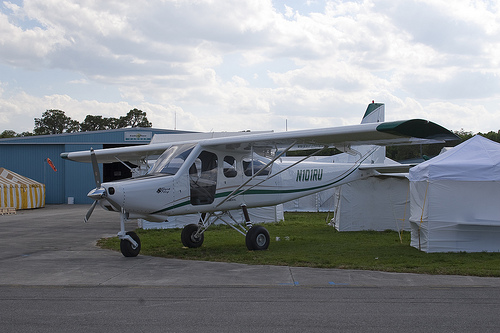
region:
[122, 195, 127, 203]
white paint on plane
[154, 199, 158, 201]
white paint on plane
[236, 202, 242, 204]
white paint on plane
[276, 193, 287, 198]
white paint on plane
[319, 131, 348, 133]
white paint on plane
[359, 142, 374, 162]
white paint on plane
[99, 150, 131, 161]
white paint on plane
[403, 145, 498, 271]
the tent is white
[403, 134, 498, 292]
the tent is white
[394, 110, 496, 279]
the tent is white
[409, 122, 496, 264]
the tent is white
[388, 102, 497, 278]
the tent is white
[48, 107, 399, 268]
a charter plane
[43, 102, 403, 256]
a charter plane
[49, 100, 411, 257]
a charter plane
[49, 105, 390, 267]
a charter plane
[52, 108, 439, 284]
a charter plane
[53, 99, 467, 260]
plane stays on ground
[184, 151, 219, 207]
plane has clear door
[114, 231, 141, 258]
wheel is attached to plane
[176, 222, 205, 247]
wheel is attached to plane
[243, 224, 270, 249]
wheel is attached to plane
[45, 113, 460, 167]
wing is attached to plane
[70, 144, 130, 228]
propeller is attached to plane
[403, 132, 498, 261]
tent is next to plane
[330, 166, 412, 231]
tent is next to plane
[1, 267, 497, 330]
ground is paved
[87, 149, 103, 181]
PROPELLAR OF AIR PL;ANE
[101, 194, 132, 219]
PROPELLAR OF AIR PLANE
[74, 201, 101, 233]
PROPELLAR OF AIR PLANE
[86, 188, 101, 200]
NOSE OF AIR PLANE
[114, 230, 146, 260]
WHEEL OF AIR PLANE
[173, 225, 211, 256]
WHEEL OF AIR PLANE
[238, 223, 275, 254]
WHEEL OF AIR PLANE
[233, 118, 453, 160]
WING OF AIR PLANE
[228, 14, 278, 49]
PUFFY CLOUDS IN THE SKY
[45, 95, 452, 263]
white plane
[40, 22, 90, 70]
white clouds in blue sky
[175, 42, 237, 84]
white clouds in blue sky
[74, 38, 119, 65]
white clouds in blue sky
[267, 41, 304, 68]
white clouds in blue sky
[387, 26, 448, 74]
white clouds in blue sky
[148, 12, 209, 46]
white clouds in blue sky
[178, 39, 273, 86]
a white fluffy cloud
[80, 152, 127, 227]
the propeller is gray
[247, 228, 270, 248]
grey rim in a wheel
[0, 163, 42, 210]
the tent is white and yellow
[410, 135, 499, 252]
the structure has a white canopy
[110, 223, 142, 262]
wheel on the pavement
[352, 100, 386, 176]
the airplane's tail section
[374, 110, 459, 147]
the wingtip is green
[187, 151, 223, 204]
the door is clear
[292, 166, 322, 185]
the lettering is green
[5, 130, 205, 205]
the building is blue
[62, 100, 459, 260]
large wide white plane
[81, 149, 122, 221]
large silver metal propeller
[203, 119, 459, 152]
large long wide white wing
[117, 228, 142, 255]
small round black wheel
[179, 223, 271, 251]
small round black wheels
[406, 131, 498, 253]
short white plastic tent